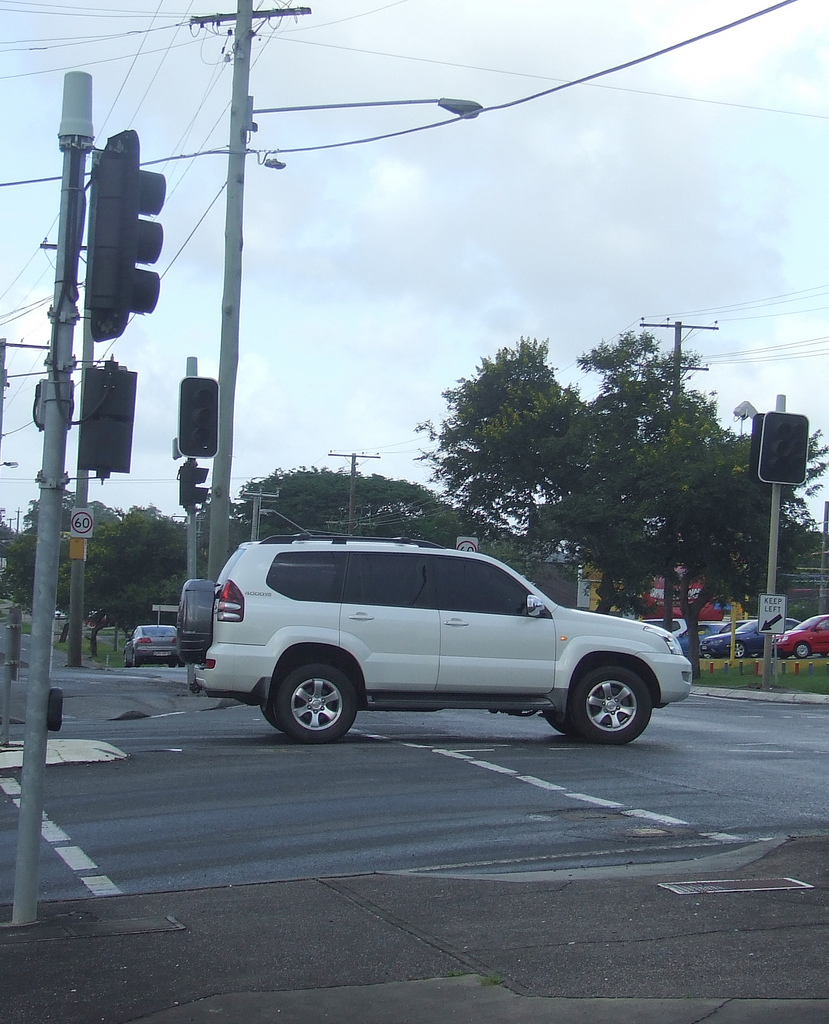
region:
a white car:
[176, 534, 688, 744]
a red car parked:
[776, 609, 821, 646]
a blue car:
[701, 608, 764, 648]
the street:
[2, 685, 820, 862]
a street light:
[59, 68, 154, 315]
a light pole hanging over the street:
[236, 90, 472, 126]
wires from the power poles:
[1, 4, 813, 285]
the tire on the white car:
[273, 666, 359, 731]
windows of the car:
[268, 548, 524, 616]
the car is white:
[149, 478, 712, 755]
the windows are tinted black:
[223, 513, 546, 629]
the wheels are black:
[260, 625, 675, 799]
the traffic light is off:
[711, 365, 804, 528]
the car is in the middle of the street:
[146, 482, 718, 807]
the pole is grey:
[1, 409, 86, 970]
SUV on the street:
[183, 526, 710, 758]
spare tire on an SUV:
[169, 571, 224, 670]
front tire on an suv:
[568, 656, 659, 748]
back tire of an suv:
[272, 648, 366, 753]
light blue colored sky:
[1, 2, 825, 531]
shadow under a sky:
[200, 725, 679, 768]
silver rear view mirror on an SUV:
[518, 590, 549, 623]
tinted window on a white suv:
[261, 546, 549, 627]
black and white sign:
[754, 589, 791, 644]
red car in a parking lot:
[769, 605, 825, 666]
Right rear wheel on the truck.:
[283, 674, 337, 733]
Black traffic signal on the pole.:
[759, 409, 811, 491]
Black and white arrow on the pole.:
[759, 570, 777, 629]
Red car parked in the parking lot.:
[792, 579, 825, 697]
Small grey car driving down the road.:
[108, 603, 193, 666]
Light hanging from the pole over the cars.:
[233, 84, 493, 126]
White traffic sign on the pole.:
[63, 491, 105, 550]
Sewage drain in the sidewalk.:
[657, 854, 825, 915]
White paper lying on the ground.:
[160, 731, 202, 761]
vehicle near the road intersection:
[172, 534, 690, 753]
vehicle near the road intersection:
[125, 625, 190, 667]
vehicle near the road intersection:
[762, 605, 824, 658]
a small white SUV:
[173, 536, 690, 740]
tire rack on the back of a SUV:
[179, 575, 215, 656]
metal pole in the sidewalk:
[15, 65, 100, 920]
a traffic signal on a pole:
[178, 373, 220, 458]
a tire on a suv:
[275, 661, 359, 745]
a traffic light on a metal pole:
[758, 410, 808, 488]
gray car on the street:
[124, 623, 185, 666]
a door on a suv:
[339, 551, 440, 691]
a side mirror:
[525, 591, 542, 617]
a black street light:
[175, 371, 223, 457]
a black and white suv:
[162, 523, 698, 745]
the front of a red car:
[769, 611, 825, 653]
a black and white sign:
[758, 596, 786, 637]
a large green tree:
[534, 317, 806, 659]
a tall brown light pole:
[635, 308, 720, 658]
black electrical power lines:
[663, 277, 826, 323]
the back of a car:
[123, 618, 185, 661]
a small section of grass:
[700, 658, 821, 691]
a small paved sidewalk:
[688, 674, 825, 708]